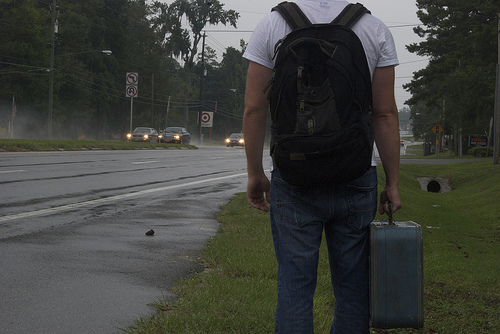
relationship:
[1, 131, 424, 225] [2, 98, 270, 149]
road has steam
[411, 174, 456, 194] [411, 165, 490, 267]
ditch in ditch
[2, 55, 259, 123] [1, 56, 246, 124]
electrical lines in a row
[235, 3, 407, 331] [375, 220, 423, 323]
man with suitcase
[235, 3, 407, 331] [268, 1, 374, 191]
man with backpack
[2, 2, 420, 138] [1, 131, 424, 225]
rain on road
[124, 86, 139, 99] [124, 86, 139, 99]
no u turn saying no u turn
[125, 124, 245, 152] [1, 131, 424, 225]
cars on road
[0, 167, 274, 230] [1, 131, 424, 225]
white line on side of road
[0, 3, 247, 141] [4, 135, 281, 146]
trees on side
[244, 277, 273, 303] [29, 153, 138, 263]
grass growing next to road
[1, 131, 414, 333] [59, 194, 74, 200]
road with water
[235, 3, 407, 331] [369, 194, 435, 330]
man has luggage